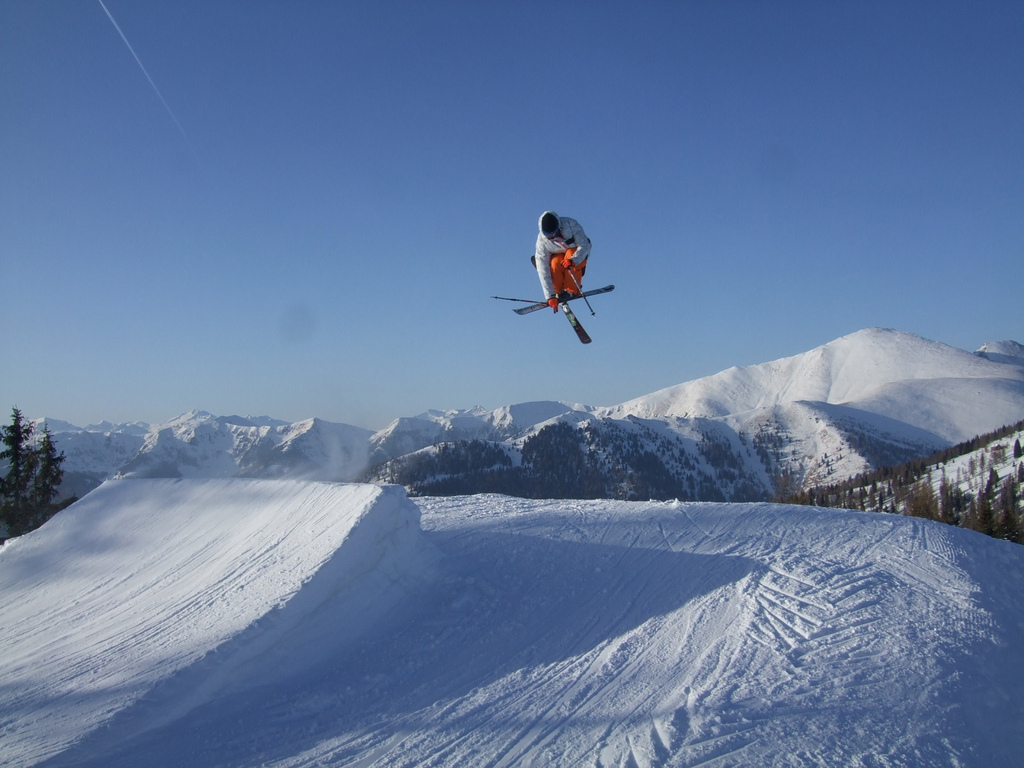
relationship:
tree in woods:
[14, 426, 66, 515] [14, 407, 153, 552]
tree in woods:
[877, 463, 955, 543] [756, 458, 1005, 515]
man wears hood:
[536, 211, 593, 314] [527, 207, 564, 233]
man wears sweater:
[536, 211, 593, 314] [531, 226, 598, 289]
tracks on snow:
[769, 557, 876, 687] [724, 538, 910, 742]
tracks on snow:
[769, 568, 829, 593] [560, 587, 656, 765]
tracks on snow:
[769, 568, 829, 593] [460, 557, 590, 765]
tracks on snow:
[233, 524, 270, 598] [151, 460, 314, 612]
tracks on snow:
[769, 568, 829, 593] [434, 497, 1022, 765]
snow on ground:
[475, 520, 970, 743] [423, 505, 981, 765]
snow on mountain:
[784, 345, 977, 400] [609, 311, 1022, 430]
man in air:
[536, 211, 593, 314] [456, 151, 683, 385]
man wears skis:
[536, 211, 593, 314] [486, 278, 616, 356]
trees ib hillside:
[456, 438, 679, 497] [352, 375, 888, 509]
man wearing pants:
[522, 197, 592, 308] [539, 243, 587, 300]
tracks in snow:
[769, 568, 829, 593] [440, 487, 944, 760]